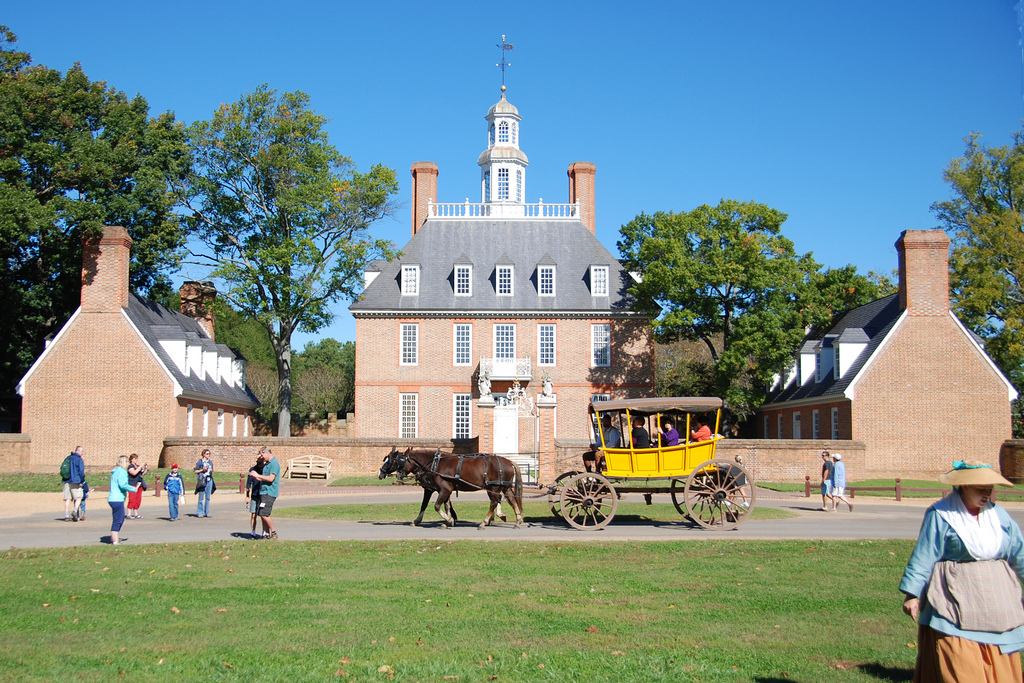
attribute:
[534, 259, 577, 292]
window — brick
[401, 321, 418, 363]
window — brick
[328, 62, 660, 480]
brick building — large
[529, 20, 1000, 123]
sky — blue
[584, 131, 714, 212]
clouds — white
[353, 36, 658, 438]
building — large 